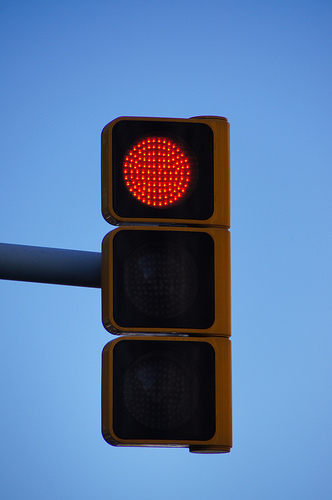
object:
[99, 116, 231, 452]
signal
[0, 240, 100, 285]
bar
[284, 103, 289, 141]
ground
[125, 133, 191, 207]
red light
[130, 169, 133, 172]
pixel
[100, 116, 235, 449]
traffic light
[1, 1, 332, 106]
blue sky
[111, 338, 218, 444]
bottom light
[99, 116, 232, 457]
light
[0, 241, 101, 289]
pole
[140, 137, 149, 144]
pixel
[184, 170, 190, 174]
pixel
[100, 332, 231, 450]
bottom